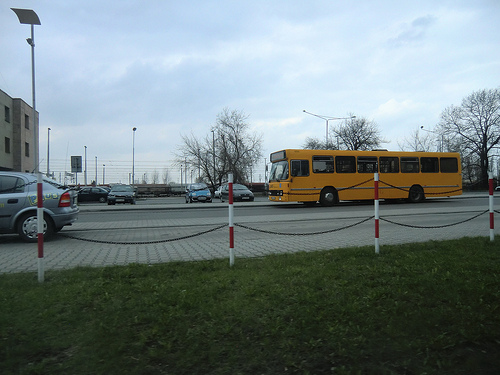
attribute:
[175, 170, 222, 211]
car — blue, mini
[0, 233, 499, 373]
bushes — very green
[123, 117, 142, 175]
lights — tall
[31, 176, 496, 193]
chain — white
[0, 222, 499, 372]
grass — green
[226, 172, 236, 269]
pole — painted, red, white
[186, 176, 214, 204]
car — blue, parked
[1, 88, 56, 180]
building — brown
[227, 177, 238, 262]
pole — red, white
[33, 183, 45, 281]
pole — red, white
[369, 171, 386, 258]
pole — red, white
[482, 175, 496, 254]
pole — red, white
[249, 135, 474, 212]
bus — yellow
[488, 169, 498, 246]
pole — white, red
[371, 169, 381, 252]
pole — white, red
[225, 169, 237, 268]
pole — white, red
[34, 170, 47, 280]
pole — white, red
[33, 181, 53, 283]
pole — white, red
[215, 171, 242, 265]
pole — white, red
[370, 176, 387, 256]
pole — white, red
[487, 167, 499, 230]
pole — white, red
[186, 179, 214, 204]
blue car — very small, parked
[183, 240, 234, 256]
sidewalk — brick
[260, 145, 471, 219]
bus — parked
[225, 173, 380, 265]
poles — white, red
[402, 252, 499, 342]
grass — portion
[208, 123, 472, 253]
bus — yellow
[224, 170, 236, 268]
post — red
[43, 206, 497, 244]
chain — metal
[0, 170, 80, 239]
car — light blue, gray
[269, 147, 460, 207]
bus — yellow, parked, long